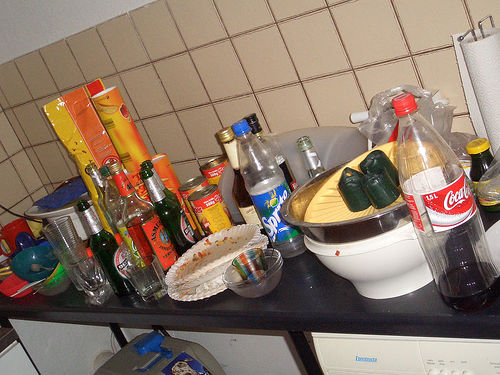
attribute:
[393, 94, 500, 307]
bottle — 1.5 liter, plastic